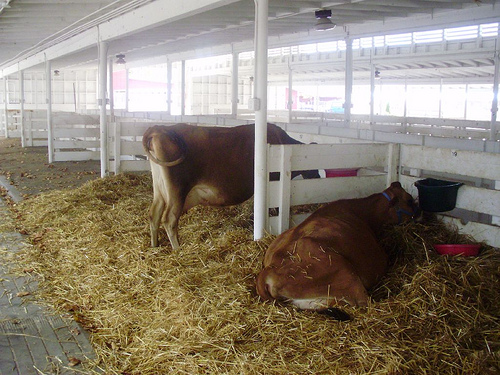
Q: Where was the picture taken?
A: In a stable.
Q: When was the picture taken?
A: Daytime.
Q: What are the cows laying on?
A: Straw.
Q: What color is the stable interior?
A: White.